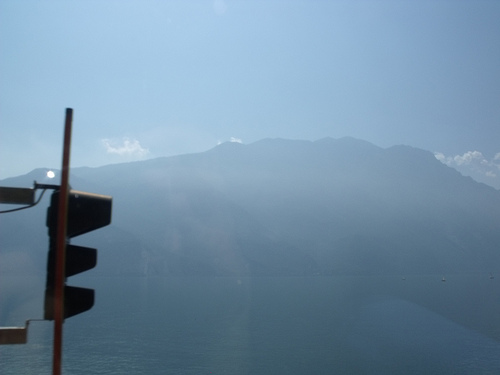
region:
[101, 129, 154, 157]
white cloud in sky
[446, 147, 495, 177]
white cloud in sky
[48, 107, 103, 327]
traffic light on pole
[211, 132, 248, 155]
small hill on mountain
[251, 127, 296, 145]
small hill on mountain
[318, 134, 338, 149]
small hill on mountain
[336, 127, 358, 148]
small hill on mountain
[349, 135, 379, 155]
small hill on mountain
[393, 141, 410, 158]
small hill on mountain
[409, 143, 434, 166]
small hill on mountain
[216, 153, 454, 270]
The mountain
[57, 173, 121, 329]
Traffic signals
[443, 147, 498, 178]
Clouds in the sky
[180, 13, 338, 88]
The sky is blue and clear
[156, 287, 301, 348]
Water is blue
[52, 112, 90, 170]
a brown pole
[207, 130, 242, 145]
Clouds by the mountain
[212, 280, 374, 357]
The water is blue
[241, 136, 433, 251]
Mountain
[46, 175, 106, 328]
Traffic signal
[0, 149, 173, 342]
a street light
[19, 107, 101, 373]
the pole of a street light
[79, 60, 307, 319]
sunlight hitting the moutain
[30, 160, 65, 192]
reflection of the sun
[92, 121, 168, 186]
small cloud behind the mountain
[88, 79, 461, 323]
a large mountain in the sky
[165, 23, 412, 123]
a blue sky with sun beams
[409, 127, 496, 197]
fluffy white clouds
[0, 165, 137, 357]
a metal light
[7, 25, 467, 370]
sunlight on the landscape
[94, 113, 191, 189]
Clouds in the sky.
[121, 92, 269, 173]
White cloud in the sky.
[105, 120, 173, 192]
White cloud in the blue sky.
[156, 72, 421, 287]
Sky with clouds in it.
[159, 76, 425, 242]
Sky with white clouds.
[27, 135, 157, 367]
Close up of traffic light.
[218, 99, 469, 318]
Mountain in the background.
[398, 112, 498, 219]
Clouds behind the mountain.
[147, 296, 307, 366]
Base of the mountain.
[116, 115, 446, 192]
Blue sky above the mountain.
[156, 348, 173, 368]
the water is blue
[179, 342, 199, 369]
the water is blue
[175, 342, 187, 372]
the water is blue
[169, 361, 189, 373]
the water is blue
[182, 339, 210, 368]
the water is blue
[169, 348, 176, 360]
the water is blue